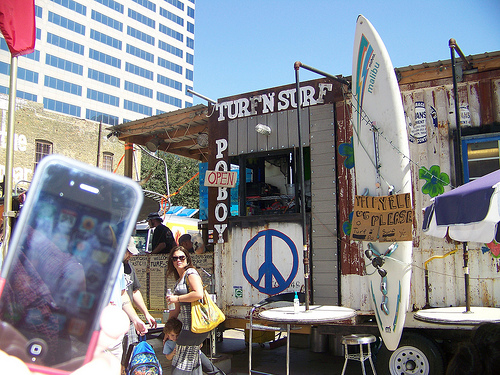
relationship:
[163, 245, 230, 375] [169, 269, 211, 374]
woman wearing dress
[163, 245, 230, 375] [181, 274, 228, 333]
woman holding purse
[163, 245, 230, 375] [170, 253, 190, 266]
woman wearing sunglasses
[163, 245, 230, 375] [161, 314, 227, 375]
woman with child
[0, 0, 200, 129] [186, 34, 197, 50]
building has window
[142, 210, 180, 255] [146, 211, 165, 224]
man wearing hat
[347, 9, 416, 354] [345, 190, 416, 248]
surfboard has sign